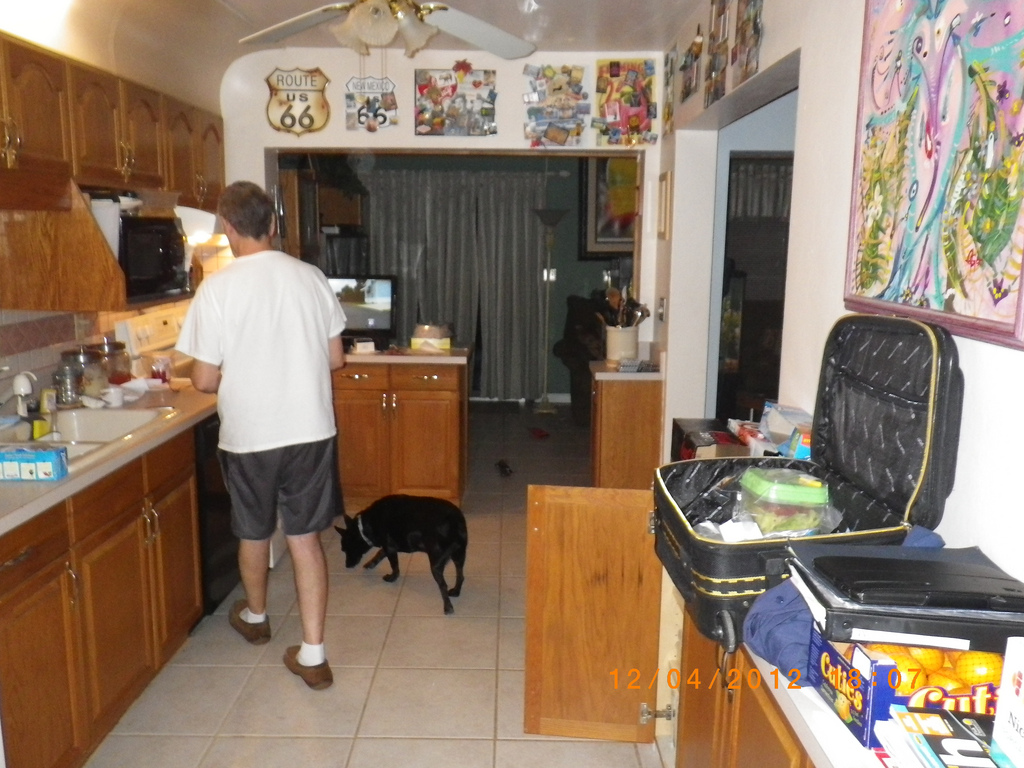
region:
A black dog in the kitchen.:
[332, 491, 466, 616]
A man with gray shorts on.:
[185, 181, 344, 690]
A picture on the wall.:
[836, 0, 1023, 351]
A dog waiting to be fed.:
[334, 475, 465, 616]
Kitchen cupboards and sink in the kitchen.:
[3, 375, 218, 764]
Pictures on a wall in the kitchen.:
[264, 49, 666, 148]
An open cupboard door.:
[528, 485, 656, 742]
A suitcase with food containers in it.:
[650, 314, 968, 631]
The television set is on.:
[340, 269, 405, 342]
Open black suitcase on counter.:
[644, 386, 869, 625]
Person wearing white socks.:
[240, 597, 330, 673]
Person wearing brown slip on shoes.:
[224, 591, 341, 708]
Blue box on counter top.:
[9, 440, 79, 488]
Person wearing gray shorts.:
[201, 436, 353, 534]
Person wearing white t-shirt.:
[170, 252, 364, 426]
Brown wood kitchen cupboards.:
[338, 369, 472, 500]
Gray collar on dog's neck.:
[348, 509, 375, 561]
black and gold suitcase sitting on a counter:
[645, 307, 969, 675]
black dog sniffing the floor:
[332, 486, 473, 613]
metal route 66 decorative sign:
[266, 59, 334, 143]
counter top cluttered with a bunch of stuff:
[734, 585, 1014, 762]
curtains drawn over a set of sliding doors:
[352, 160, 553, 408]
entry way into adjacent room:
[253, 129, 656, 497]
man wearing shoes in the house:
[179, 177, 345, 696]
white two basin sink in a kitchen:
[2, 392, 186, 500]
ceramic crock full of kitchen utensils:
[593, 277, 648, 370]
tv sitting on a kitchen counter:
[321, 266, 407, 343]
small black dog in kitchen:
[333, 471, 518, 607]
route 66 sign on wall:
[254, 61, 337, 129]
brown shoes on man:
[220, 564, 345, 713]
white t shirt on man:
[200, 264, 355, 433]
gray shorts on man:
[229, 444, 335, 533]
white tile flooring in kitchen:
[229, 357, 613, 766]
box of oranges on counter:
[818, 640, 983, 733]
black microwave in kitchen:
[78, 206, 196, 304]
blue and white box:
[7, 452, 64, 466]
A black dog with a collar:
[324, 487, 468, 614]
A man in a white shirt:
[182, 180, 348, 687]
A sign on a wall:
[256, 67, 327, 143]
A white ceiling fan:
[231, 2, 533, 67]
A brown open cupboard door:
[517, 484, 655, 748]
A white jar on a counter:
[602, 323, 632, 363]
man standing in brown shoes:
[182, 182, 350, 694]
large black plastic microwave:
[80, 197, 186, 314]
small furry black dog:
[331, 501, 481, 616]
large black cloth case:
[649, 311, 966, 654]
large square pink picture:
[845, 3, 1020, 349]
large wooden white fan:
[235, 0, 542, 63]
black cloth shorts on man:
[219, 436, 344, 541]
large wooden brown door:
[521, 483, 670, 750]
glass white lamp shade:
[340, 3, 411, 46]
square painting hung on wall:
[410, 61, 510, 142]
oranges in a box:
[838, 617, 1009, 700]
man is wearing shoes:
[281, 607, 346, 703]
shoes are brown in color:
[280, 639, 358, 704]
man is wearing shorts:
[223, 443, 405, 571]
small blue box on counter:
[6, 430, 70, 476]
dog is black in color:
[347, 483, 477, 604]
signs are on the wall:
[287, 111, 665, 140]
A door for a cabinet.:
[157, 96, 203, 210]